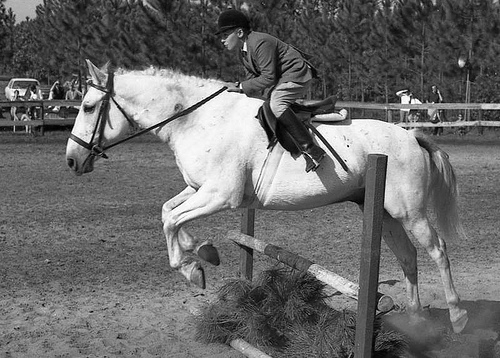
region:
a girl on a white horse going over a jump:
[63, 8, 469, 349]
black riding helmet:
[213, 7, 250, 33]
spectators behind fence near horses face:
[8, 78, 80, 132]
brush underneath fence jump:
[194, 263, 401, 356]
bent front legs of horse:
[157, 183, 250, 294]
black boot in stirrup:
[275, 106, 326, 173]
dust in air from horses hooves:
[387, 283, 485, 353]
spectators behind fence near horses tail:
[394, 82, 446, 127]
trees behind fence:
[0, 0, 497, 103]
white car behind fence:
[3, 75, 43, 101]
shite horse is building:
[68, 51, 475, 329]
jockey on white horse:
[211, 16, 333, 173]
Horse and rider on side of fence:
[392, 84, 450, 144]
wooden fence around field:
[349, 96, 498, 141]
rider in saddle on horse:
[214, 13, 339, 164]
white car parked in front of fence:
[6, 72, 45, 105]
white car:
[9, 76, 51, 108]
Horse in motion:
[62, 61, 479, 339]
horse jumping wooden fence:
[229, 155, 389, 353]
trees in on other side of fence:
[11, 7, 498, 99]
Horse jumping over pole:
[30, 26, 492, 316]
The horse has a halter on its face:
[45, 60, 127, 175]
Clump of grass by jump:
[198, 264, 336, 344]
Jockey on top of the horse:
[201, 12, 351, 181]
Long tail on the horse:
[390, 115, 475, 244]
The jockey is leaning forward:
[204, 12, 343, 217]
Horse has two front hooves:
[168, 226, 233, 291]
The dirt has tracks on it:
[14, 184, 136, 356]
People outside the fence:
[390, 67, 465, 130]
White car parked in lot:
[3, 62, 56, 114]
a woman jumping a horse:
[41, 7, 476, 350]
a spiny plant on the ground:
[240, 273, 320, 339]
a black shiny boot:
[280, 109, 327, 176]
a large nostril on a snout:
[67, 155, 86, 175]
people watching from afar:
[394, 82, 450, 127]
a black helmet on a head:
[213, 6, 251, 31]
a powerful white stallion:
[60, 64, 249, 202]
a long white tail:
[439, 156, 469, 248]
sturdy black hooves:
[190, 247, 222, 294]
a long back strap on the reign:
[186, 92, 228, 112]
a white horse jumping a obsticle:
[40, 73, 458, 293]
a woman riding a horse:
[30, 28, 352, 255]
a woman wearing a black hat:
[209, 9, 264, 61]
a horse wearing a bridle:
[38, 62, 238, 189]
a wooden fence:
[309, 99, 480, 129]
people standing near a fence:
[376, 76, 468, 130]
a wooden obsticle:
[220, 134, 403, 349]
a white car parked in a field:
[2, 70, 50, 105]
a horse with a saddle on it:
[184, 71, 413, 191]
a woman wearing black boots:
[280, 81, 337, 188]